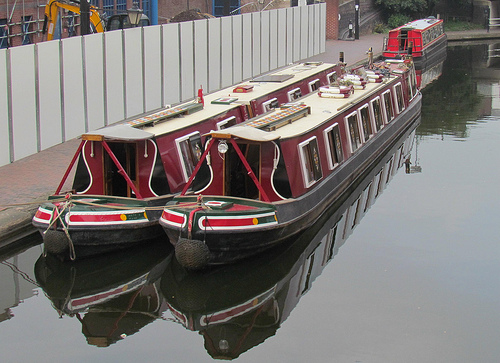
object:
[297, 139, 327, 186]
window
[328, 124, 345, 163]
window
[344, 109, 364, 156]
window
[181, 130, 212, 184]
window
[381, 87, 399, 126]
window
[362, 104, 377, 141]
window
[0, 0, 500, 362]
scene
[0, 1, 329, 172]
fence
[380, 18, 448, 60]
boat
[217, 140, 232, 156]
boat